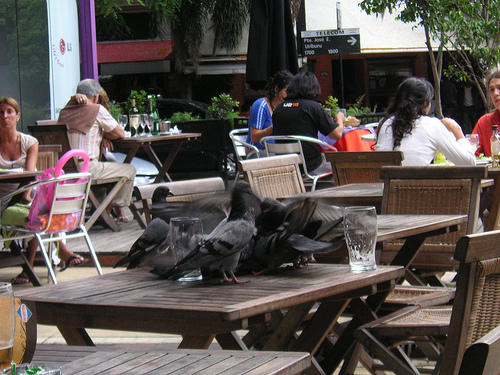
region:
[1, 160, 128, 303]
this is a white chair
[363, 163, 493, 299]
this is a brown chair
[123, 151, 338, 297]
these are the birds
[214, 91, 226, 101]
this is a leaf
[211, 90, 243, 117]
these are the leaves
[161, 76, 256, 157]
this is a bush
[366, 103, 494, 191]
this is a white shirt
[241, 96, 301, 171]
this is a blue shirt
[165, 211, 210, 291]
an empty glass on a table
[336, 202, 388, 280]
an empty glass on a table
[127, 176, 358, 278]
a group of pigeons on a table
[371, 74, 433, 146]
a person with long brown hair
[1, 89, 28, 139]
the head of a woman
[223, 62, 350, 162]
a couple sitting at a table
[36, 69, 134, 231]
a man sitting at table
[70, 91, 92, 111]
a had of a person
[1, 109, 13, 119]
the nose of a person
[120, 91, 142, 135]
a bottle of wine on a table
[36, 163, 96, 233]
a pink bag sitting on a chair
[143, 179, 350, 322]
pegions sitting on table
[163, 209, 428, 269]
glasses sitting with piegons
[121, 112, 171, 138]
wine glasses sitting on a table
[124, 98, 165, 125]
wine bottles sitting with wine glasses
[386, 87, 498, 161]
people sitting at the table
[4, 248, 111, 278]
woman wearing flip flops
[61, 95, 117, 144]
a person wearing a sweater on shoulders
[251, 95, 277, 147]
a person wearing a blue shirt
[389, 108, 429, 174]
a person wearing white shirt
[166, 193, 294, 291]
birds on the bench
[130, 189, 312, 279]
birds on the bench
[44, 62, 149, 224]
this is a person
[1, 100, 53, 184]
this is a person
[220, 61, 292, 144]
this is a person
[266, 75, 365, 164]
this is a person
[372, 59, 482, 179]
this is a person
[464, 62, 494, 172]
this is a person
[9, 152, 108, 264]
this is a chair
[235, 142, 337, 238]
this is a chair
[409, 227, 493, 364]
this is a chair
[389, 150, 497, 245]
this is a chair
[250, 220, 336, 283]
pigeon on the wooden table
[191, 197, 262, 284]
pigeon on the wooden table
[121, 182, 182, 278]
pigeon on the wooden table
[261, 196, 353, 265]
pigeon on the wooden table